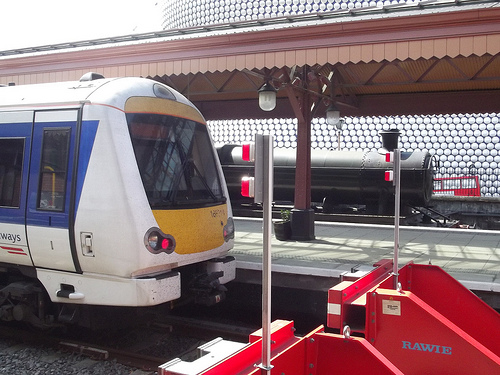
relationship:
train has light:
[0, 72, 236, 335] [146, 228, 161, 255]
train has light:
[0, 72, 236, 335] [227, 218, 236, 240]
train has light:
[0, 72, 236, 335] [153, 82, 176, 99]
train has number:
[0, 72, 236, 335] [209, 206, 229, 218]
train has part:
[0, 72, 236, 335] [0, 283, 46, 322]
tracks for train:
[34, 315, 262, 370] [0, 72, 236, 335]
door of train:
[25, 107, 82, 273] [0, 72, 236, 335]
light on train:
[146, 228, 161, 255] [0, 72, 236, 335]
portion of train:
[125, 97, 230, 257] [0, 72, 236, 335]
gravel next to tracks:
[0, 340, 157, 374] [34, 315, 262, 370]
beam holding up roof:
[293, 70, 315, 240] [0, 1, 499, 119]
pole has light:
[262, 133, 273, 374] [241, 177, 252, 199]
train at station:
[0, 72, 236, 335] [2, 52, 499, 372]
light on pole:
[241, 177, 252, 199] [262, 133, 273, 374]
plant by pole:
[274, 207, 294, 241] [293, 70, 315, 240]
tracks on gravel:
[34, 315, 262, 370] [0, 340, 157, 374]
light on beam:
[325, 102, 341, 127] [293, 70, 315, 240]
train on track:
[0, 72, 236, 335] [34, 315, 262, 370]